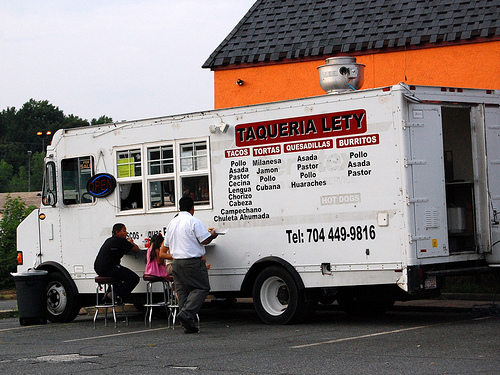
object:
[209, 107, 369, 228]
menu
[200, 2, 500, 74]
roof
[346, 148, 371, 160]
word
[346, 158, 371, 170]
word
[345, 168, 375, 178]
word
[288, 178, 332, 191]
word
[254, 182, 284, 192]
word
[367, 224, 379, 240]
number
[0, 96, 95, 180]
trees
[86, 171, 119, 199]
hat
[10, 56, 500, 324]
truck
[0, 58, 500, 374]
parking lot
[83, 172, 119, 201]
sign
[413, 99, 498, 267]
open door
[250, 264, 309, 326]
tire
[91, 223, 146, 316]
people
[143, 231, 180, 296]
girl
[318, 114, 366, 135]
words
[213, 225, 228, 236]
food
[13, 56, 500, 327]
food truck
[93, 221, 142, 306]
customers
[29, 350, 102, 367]
hole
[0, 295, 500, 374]
asphalt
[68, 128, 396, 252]
side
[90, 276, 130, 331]
stool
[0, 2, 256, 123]
sky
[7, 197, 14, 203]
leaves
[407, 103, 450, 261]
door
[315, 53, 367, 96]
exhaust fan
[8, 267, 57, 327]
garbage can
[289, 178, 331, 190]
writing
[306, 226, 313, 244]
number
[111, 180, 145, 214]
window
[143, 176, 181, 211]
window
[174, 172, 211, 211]
window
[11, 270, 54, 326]
trash can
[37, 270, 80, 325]
tire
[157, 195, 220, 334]
man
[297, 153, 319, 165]
food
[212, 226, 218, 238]
hands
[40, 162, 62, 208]
side mirrors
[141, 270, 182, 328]
stool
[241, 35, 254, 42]
shingles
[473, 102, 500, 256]
door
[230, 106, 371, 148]
sign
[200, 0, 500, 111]
building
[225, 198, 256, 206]
menu items